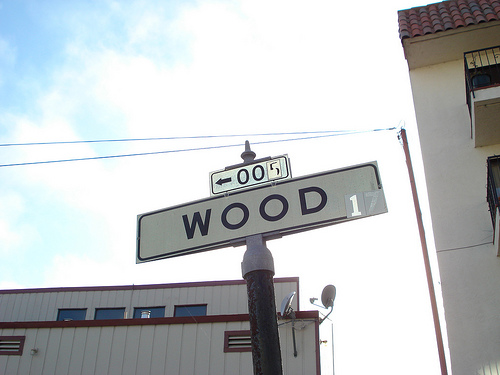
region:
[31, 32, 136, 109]
white clouds in blue sky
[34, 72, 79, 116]
white clouds in blue sky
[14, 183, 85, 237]
white clouds in blue sky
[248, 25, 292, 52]
white clouds in blue sky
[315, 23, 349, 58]
white clouds in blue sky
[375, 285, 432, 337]
white clouds in blue sky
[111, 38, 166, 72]
white clouds in blue sky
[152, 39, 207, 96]
white clouds in blue sky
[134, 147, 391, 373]
street sign on top of pole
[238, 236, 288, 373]
pole is black with white sign holder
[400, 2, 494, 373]
white building with red roof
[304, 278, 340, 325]
satellite dish on side of building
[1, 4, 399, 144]
partially clouded blue sky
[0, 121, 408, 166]
utility wires on top of pole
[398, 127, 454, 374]
tall wooden utility pole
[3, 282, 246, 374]
white and red structure with small windows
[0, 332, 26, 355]
red and white vent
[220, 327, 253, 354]
red and white vent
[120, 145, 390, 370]
white and black street sign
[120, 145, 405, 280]
street sign on top of pole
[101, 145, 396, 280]
black and white street sign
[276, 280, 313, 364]
metal dish on side of roof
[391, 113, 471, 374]
utility pole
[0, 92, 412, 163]
utility line attached to pole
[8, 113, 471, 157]
electric utilty line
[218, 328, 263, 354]
vent on side of building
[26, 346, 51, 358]
light attached to side of building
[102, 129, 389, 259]
white and black street sign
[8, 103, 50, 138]
white clouds in blue sky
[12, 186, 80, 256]
white clouds in blue sky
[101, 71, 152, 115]
white clouds in blue sky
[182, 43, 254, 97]
white clouds in blue sky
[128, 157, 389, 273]
the sign is white and black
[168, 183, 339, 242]
black letters on sign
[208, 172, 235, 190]
black arrow on sign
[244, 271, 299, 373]
sign post is black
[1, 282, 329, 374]
frame around building is brown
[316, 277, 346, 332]
satellite dish on building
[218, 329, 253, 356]
vent on the building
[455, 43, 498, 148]
balcony on the building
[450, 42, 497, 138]
balcony railing is black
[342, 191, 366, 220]
white number on sign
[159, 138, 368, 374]
a sign on the metla pole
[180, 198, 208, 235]
w on th esign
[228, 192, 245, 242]
o on the sign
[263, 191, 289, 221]
o on the signn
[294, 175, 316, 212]
d on the sign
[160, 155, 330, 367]
metal pole with sign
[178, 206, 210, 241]
black letter on sign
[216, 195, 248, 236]
black letter on sign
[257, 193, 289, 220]
black letter on sign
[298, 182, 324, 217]
black letter on sign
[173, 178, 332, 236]
black letters on sign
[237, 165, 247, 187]
black numer on sign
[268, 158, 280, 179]
black numer on sign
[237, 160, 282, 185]
black numbers on sign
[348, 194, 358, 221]
white number on sign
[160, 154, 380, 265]
a sign on the pole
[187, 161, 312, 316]
a sign on a metal pole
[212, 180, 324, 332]
a street sign on the pole